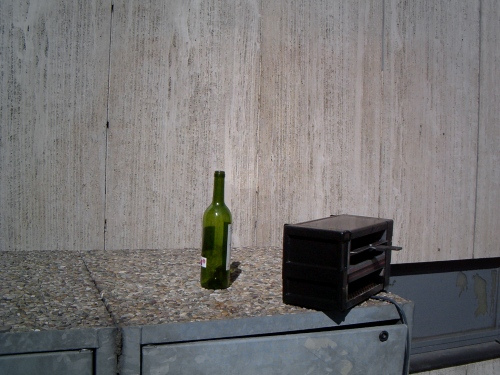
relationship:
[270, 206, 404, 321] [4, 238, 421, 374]
black object on counter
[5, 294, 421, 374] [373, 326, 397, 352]
cabinet has lock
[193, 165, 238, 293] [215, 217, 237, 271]
bottle has label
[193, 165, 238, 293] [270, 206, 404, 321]
bottle next to black object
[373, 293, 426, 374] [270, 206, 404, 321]
cord from black object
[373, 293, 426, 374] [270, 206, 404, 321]
cord for black object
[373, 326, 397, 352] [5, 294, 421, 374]
lock for cabinet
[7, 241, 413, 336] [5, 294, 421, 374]
stone tops are on cabinet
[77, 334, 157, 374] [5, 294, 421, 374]
hinges for cabinet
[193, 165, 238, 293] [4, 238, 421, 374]
bottle on counter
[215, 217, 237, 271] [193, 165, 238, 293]
label on bottle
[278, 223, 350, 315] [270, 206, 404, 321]
back of black object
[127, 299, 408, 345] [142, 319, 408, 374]
top of cabinet door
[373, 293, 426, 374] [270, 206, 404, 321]
cord attached to black object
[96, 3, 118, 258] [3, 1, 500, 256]
line on wall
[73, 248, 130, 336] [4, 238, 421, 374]
crack on counter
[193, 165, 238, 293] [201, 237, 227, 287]
bottle of wine